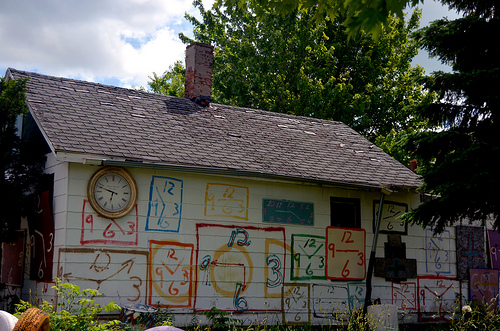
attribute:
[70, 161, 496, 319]
wall — full, white, drawn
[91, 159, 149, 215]
clock — graffiti, outdoor, here, drawn, orange, red, circular, brown, green, blue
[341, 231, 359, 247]
number — drawn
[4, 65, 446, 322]
house — shingled, present, entrance, covered, abandoned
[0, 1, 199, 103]
clouds — white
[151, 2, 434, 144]
tree — growing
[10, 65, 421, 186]
roof — brown, shingled, wooden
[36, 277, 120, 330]
bushes — green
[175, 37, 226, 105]
chimney — tall, present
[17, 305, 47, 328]
wheel — brown, old